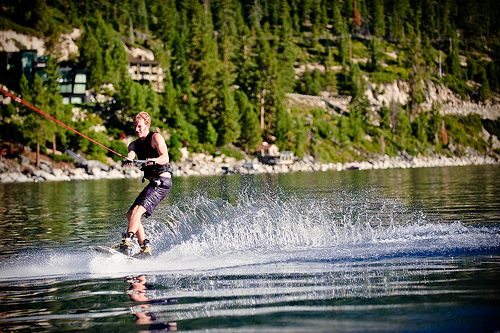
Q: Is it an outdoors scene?
A: Yes, it is outdoors.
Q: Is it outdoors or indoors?
A: It is outdoors.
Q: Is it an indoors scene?
A: No, it is outdoors.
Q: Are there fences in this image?
A: No, there are no fences.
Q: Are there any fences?
A: No, there are no fences.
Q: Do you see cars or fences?
A: No, there are no fences or cars.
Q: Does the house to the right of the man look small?
A: Yes, the house is small.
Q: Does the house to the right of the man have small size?
A: Yes, the house is small.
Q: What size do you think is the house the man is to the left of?
A: The house is small.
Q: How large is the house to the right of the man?
A: The house is small.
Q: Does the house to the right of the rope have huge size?
A: No, the house is small.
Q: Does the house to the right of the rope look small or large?
A: The house is small.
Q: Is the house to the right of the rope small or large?
A: The house is small.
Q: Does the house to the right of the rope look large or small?
A: The house is small.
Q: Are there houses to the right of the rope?
A: Yes, there is a house to the right of the rope.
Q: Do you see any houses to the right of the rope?
A: Yes, there is a house to the right of the rope.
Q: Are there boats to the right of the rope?
A: No, there is a house to the right of the rope.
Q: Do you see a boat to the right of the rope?
A: No, there is a house to the right of the rope.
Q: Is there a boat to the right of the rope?
A: No, there is a house to the right of the rope.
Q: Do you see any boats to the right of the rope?
A: No, there is a house to the right of the rope.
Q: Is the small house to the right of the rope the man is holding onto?
A: Yes, the house is to the right of the rope.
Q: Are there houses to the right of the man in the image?
A: Yes, there is a house to the right of the man.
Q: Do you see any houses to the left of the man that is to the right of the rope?
A: No, the house is to the right of the man.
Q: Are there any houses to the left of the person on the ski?
A: No, the house is to the right of the man.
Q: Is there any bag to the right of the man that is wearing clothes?
A: No, there is a house to the right of the man.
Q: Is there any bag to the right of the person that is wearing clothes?
A: No, there is a house to the right of the man.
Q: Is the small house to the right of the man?
A: Yes, the house is to the right of the man.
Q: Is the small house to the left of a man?
A: No, the house is to the right of a man.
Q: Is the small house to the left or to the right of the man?
A: The house is to the right of the man.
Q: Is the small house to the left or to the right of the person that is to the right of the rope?
A: The house is to the right of the man.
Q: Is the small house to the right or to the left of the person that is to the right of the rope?
A: The house is to the right of the man.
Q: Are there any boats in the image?
A: No, there are no boats.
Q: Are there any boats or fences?
A: No, there are no boats or fences.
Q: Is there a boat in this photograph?
A: No, there are no boats.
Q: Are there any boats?
A: No, there are no boats.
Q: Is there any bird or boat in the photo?
A: No, there are no boats or birds.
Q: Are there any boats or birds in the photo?
A: No, there are no boats or birds.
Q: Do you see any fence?
A: No, there are no fences.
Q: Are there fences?
A: No, there are no fences.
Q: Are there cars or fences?
A: No, there are no fences or cars.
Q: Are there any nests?
A: No, there are no nests.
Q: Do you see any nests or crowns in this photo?
A: No, there are no nests or crowns.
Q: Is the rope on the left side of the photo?
A: Yes, the rope is on the left of the image.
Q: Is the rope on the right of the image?
A: No, the rope is on the left of the image.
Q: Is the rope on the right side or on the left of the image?
A: The rope is on the left of the image.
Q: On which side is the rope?
A: The rope is on the left of the image.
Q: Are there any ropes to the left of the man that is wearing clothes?
A: Yes, there is a rope to the left of the man.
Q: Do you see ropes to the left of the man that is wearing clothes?
A: Yes, there is a rope to the left of the man.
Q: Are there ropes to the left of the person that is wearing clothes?
A: Yes, there is a rope to the left of the man.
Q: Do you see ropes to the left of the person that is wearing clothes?
A: Yes, there is a rope to the left of the man.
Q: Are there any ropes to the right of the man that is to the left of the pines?
A: No, the rope is to the left of the man.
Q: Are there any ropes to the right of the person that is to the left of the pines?
A: No, the rope is to the left of the man.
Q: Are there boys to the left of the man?
A: No, there is a rope to the left of the man.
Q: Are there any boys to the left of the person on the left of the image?
A: No, there is a rope to the left of the man.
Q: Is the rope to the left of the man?
A: Yes, the rope is to the left of the man.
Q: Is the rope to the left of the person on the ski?
A: Yes, the rope is to the left of the man.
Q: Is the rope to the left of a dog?
A: No, the rope is to the left of the man.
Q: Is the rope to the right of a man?
A: No, the rope is to the left of a man.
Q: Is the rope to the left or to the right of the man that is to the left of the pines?
A: The rope is to the left of the man.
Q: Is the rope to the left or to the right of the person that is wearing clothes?
A: The rope is to the left of the man.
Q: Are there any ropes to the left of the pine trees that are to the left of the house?
A: Yes, there is a rope to the left of the pines.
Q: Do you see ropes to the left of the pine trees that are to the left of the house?
A: Yes, there is a rope to the left of the pines.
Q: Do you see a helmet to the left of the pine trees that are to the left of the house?
A: No, there is a rope to the left of the pine trees.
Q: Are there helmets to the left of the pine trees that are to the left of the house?
A: No, there is a rope to the left of the pine trees.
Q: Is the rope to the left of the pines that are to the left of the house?
A: Yes, the rope is to the left of the pines.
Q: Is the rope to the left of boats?
A: No, the rope is to the left of the pines.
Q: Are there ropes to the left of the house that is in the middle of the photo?
A: Yes, there is a rope to the left of the house.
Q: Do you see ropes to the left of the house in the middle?
A: Yes, there is a rope to the left of the house.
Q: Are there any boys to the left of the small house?
A: No, there is a rope to the left of the house.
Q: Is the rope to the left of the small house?
A: Yes, the rope is to the left of the house.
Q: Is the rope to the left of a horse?
A: No, the rope is to the left of the house.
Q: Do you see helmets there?
A: No, there are no helmets.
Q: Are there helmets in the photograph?
A: No, there are no helmets.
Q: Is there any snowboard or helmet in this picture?
A: No, there are no helmets or snowboards.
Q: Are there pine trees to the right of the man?
A: Yes, there are pine trees to the right of the man.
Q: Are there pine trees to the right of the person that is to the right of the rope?
A: Yes, there are pine trees to the right of the man.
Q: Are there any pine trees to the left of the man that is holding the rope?
A: No, the pine trees are to the right of the man.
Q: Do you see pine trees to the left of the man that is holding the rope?
A: No, the pine trees are to the right of the man.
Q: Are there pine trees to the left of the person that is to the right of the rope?
A: No, the pine trees are to the right of the man.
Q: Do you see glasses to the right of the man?
A: No, there are pine trees to the right of the man.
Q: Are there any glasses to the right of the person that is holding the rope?
A: No, there are pine trees to the right of the man.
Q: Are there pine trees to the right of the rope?
A: Yes, there are pine trees to the right of the rope.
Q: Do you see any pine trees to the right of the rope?
A: Yes, there are pine trees to the right of the rope.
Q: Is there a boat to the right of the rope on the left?
A: No, there are pine trees to the right of the rope.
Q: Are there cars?
A: No, there are no cars.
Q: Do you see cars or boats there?
A: No, there are no cars or boats.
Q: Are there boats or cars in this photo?
A: No, there are no cars or boats.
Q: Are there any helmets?
A: No, there are no helmets.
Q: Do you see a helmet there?
A: No, there are no helmets.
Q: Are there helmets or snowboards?
A: No, there are no helmets or snowboards.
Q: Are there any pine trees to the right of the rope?
A: Yes, there are pine trees to the right of the rope.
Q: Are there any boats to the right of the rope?
A: No, there are pine trees to the right of the rope.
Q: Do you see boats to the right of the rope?
A: No, there are pine trees to the right of the rope.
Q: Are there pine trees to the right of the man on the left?
A: Yes, there are pine trees to the right of the man.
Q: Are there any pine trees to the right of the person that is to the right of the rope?
A: Yes, there are pine trees to the right of the man.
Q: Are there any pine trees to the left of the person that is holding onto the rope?
A: No, the pine trees are to the right of the man.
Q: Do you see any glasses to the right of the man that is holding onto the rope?
A: No, there are pine trees to the right of the man.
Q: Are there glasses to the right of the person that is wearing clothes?
A: No, there are pine trees to the right of the man.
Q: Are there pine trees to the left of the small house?
A: Yes, there are pine trees to the left of the house.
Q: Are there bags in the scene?
A: No, there are no bags.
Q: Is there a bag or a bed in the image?
A: No, there are no bags or beds.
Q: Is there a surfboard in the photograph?
A: Yes, there is a surfboard.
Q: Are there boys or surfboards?
A: Yes, there is a surfboard.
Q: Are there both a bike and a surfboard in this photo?
A: No, there is a surfboard but no bikes.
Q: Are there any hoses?
A: No, there are no hoses.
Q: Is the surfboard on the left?
A: Yes, the surfboard is on the left of the image.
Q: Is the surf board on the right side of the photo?
A: No, the surf board is on the left of the image.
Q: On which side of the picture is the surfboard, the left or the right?
A: The surfboard is on the left of the image.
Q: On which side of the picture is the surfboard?
A: The surfboard is on the left of the image.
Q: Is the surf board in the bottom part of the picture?
A: Yes, the surf board is in the bottom of the image.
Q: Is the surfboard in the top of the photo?
A: No, the surfboard is in the bottom of the image.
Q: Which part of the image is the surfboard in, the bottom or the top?
A: The surfboard is in the bottom of the image.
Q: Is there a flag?
A: No, there are no flags.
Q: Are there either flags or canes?
A: No, there are no flags or canes.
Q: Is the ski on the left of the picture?
A: Yes, the ski is on the left of the image.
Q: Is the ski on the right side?
A: No, the ski is on the left of the image.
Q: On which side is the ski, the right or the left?
A: The ski is on the left of the image.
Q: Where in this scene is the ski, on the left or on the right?
A: The ski is on the left of the image.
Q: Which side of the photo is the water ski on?
A: The ski is on the left of the image.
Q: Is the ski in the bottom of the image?
A: Yes, the ski is in the bottom of the image.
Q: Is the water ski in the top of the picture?
A: No, the ski is in the bottom of the image.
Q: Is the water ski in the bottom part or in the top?
A: The ski is in the bottom of the image.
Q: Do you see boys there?
A: No, there are no boys.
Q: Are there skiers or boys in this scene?
A: No, there are no boys or skiers.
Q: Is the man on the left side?
A: Yes, the man is on the left of the image.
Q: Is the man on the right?
A: No, the man is on the left of the image.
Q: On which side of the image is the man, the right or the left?
A: The man is on the left of the image.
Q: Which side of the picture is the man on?
A: The man is on the left of the image.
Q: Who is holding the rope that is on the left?
A: The man is holding the rope.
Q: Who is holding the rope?
A: The man is holding the rope.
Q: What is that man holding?
A: The man is holding the rope.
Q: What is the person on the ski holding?
A: The man is holding the rope.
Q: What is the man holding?
A: The man is holding the rope.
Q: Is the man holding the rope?
A: Yes, the man is holding the rope.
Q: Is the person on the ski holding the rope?
A: Yes, the man is holding the rope.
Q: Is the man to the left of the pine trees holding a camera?
A: No, the man is holding the rope.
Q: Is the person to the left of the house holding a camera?
A: No, the man is holding the rope.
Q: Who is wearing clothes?
A: The man is wearing clothes.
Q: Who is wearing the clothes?
A: The man is wearing clothes.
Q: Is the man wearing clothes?
A: Yes, the man is wearing clothes.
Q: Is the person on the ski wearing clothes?
A: Yes, the man is wearing clothes.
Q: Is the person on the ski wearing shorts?
A: No, the man is wearing clothes.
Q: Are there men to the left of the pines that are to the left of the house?
A: Yes, there is a man to the left of the pine trees.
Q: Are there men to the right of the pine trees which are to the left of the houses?
A: No, the man is to the left of the pine trees.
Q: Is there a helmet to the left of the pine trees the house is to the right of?
A: No, there is a man to the left of the pine trees.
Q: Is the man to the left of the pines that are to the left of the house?
A: Yes, the man is to the left of the pine trees.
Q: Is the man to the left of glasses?
A: No, the man is to the left of the pine trees.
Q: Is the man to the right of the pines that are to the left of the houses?
A: No, the man is to the left of the pine trees.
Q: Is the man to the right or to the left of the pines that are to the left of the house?
A: The man is to the left of the pines.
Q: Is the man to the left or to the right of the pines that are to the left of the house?
A: The man is to the left of the pines.